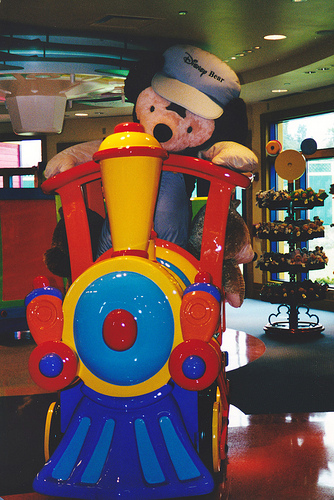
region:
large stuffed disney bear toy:
[28, 33, 260, 280]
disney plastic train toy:
[35, 186, 266, 491]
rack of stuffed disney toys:
[257, 141, 319, 330]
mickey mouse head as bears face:
[112, 74, 222, 164]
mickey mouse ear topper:
[256, 132, 321, 183]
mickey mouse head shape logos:
[259, 310, 325, 332]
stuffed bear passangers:
[8, 190, 263, 305]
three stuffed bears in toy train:
[24, 18, 277, 301]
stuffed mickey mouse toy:
[314, 240, 326, 262]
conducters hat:
[125, 43, 266, 133]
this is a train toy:
[10, 213, 201, 484]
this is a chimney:
[103, 125, 157, 238]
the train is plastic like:
[13, 164, 208, 495]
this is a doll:
[142, 53, 231, 133]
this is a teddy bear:
[180, 116, 200, 137]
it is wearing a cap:
[163, 55, 224, 98]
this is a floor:
[248, 425, 320, 498]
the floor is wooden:
[256, 425, 313, 493]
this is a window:
[302, 114, 325, 132]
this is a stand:
[286, 279, 301, 317]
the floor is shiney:
[253, 424, 315, 479]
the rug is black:
[270, 357, 313, 388]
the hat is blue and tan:
[154, 40, 237, 116]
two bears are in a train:
[10, 50, 264, 488]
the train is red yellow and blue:
[17, 112, 247, 494]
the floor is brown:
[255, 442, 298, 470]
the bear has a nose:
[250, 244, 261, 264]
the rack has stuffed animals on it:
[262, 137, 325, 348]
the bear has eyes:
[143, 102, 201, 136]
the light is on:
[252, 20, 297, 59]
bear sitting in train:
[108, 49, 230, 176]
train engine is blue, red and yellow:
[73, 135, 188, 471]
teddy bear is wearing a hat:
[156, 55, 187, 108]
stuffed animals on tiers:
[267, 187, 302, 288]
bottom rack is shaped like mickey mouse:
[268, 298, 318, 330]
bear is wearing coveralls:
[167, 132, 185, 219]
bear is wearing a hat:
[136, 33, 231, 135]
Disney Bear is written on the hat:
[167, 39, 232, 89]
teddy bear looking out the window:
[197, 189, 247, 301]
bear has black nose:
[151, 119, 172, 150]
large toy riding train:
[37, 147, 238, 419]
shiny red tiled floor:
[271, 443, 320, 492]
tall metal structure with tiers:
[277, 121, 314, 329]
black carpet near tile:
[267, 364, 304, 386]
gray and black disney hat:
[147, 52, 234, 110]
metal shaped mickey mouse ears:
[249, 305, 329, 336]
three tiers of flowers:
[265, 187, 332, 288]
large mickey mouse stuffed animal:
[92, 83, 211, 268]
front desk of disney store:
[3, 185, 32, 328]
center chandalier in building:
[15, 81, 84, 127]